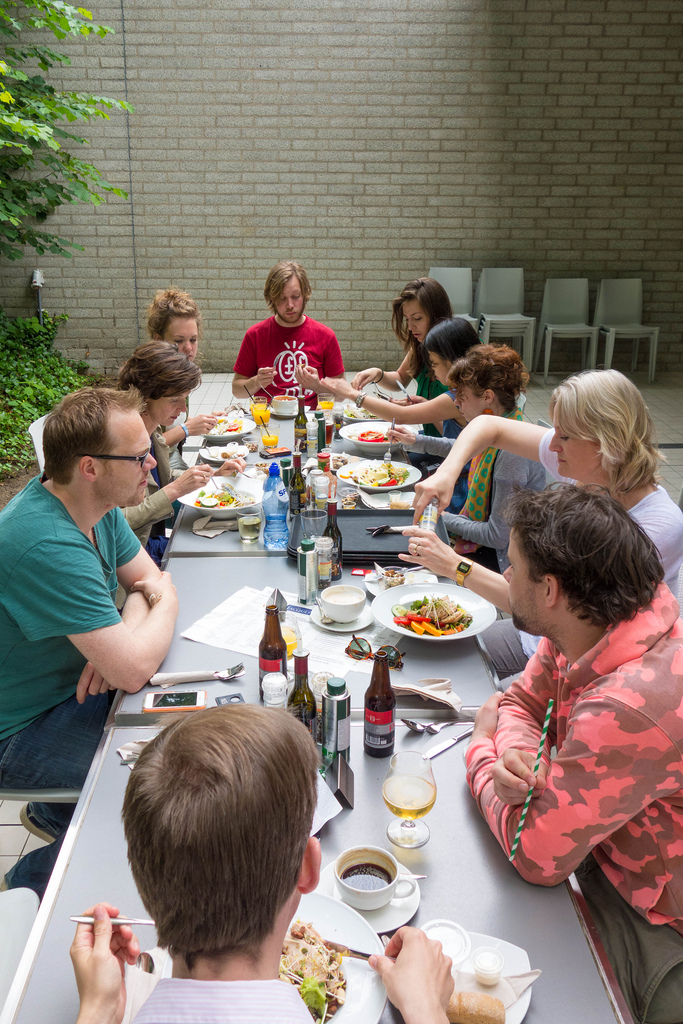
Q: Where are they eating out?
A: At a restaurant.